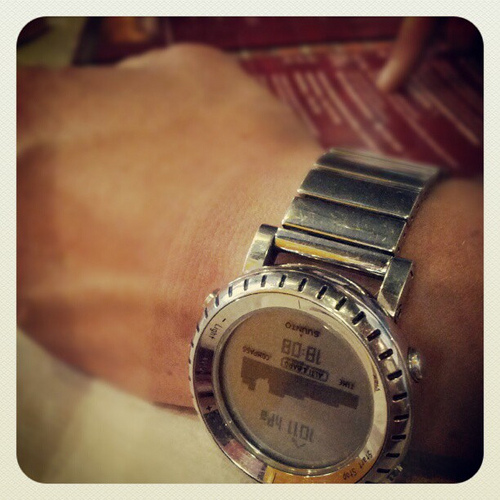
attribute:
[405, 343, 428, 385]
screw — silver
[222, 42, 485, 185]
paper — red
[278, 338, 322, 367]
black letters —  black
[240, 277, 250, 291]
line — black 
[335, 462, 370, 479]
tent —  gold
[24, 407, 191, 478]
table — white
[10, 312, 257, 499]
table — white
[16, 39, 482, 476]
skin — light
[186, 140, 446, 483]
silver watch — shiny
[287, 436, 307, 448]
arrow —  black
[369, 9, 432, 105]
finger — blurry 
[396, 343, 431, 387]
knob —   silver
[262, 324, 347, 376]
letters — black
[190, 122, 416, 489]
watch — metallic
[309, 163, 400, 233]
links — silver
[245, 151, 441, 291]
bracket — silver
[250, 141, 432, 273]
band — silver